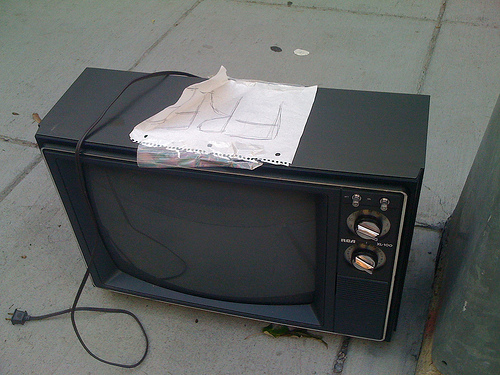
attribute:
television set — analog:
[32, 64, 431, 345]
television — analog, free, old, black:
[26, 58, 431, 348]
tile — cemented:
[122, 3, 442, 97]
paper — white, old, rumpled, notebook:
[122, 59, 323, 168]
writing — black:
[159, 87, 289, 147]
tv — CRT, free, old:
[29, 59, 432, 353]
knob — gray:
[338, 240, 388, 276]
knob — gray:
[342, 209, 397, 242]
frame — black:
[30, 64, 431, 193]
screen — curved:
[68, 154, 321, 328]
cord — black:
[1, 68, 201, 372]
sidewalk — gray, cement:
[2, 3, 483, 373]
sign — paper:
[123, 60, 319, 170]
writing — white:
[334, 232, 362, 254]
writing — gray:
[152, 86, 285, 145]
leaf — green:
[242, 320, 336, 352]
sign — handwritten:
[126, 63, 319, 162]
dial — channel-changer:
[345, 209, 386, 245]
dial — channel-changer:
[349, 242, 384, 275]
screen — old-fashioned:
[97, 160, 327, 308]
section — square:
[114, 3, 455, 93]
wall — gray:
[423, 105, 496, 370]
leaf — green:
[256, 318, 328, 348]